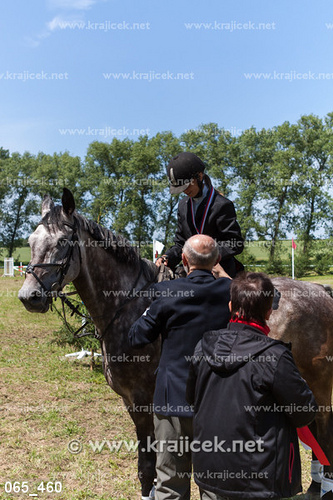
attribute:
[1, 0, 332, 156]
sky — blue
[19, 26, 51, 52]
cloud — white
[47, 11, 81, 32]
cloud — white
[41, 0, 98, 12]
cloud — white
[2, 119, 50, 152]
cloud — white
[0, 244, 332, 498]
grass — dying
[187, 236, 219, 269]
man — bald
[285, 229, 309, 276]
flag — orange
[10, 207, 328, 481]
horse — gray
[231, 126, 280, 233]
leaves — green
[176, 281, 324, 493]
jacket — black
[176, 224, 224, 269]
head — balding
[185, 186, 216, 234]
metal — red, white, blue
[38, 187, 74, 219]
ears — pointed, upright, horse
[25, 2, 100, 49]
clouds — white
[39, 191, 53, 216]
ear — grey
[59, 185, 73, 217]
ear — black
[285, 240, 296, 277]
pole — grey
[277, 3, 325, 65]
sky — blue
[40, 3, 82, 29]
clouds — white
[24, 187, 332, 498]
horse — brown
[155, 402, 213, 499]
pants — gray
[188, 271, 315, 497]
person — red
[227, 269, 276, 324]
hair — brown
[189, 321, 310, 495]
jacket — black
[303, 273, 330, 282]
grass — brown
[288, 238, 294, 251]
flag — red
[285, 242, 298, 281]
pole — metal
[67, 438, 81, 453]
copyright symbol — grey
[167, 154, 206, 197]
hat — black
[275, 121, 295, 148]
leaves — green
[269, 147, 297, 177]
leaves — green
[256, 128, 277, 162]
leaves — green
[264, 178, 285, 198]
leaves — green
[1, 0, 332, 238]
sky — blue, clear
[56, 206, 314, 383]
horse — black, grey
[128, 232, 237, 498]
balding man — in the picture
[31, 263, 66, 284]
harnass — black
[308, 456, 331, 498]
wraps — white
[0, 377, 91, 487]
grass — green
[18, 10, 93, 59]
clouds — white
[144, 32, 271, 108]
sky — blue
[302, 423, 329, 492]
leg — brownish 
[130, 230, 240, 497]
man — gray-haired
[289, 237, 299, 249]
flag — red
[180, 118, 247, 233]
tree — tall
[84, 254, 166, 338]
reins — dark